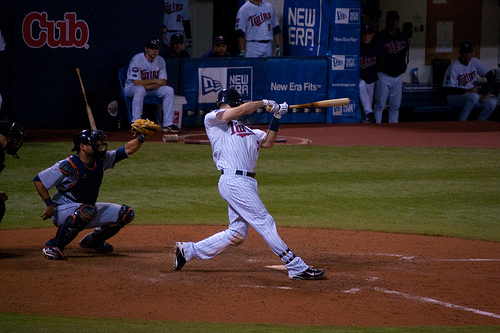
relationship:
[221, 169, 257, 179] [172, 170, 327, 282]
belt in pants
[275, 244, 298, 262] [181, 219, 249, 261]
bands around leg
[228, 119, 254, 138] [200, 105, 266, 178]
name on shirt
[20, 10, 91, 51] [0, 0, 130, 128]
print on wall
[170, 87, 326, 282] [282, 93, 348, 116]
batter holds bat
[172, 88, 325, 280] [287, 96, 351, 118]
batter swings bat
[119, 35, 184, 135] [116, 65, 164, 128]
players in chair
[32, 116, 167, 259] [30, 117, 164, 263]
catcher wears catcher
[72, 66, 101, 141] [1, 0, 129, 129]
bat leans against wall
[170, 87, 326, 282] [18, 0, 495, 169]
batter in dug out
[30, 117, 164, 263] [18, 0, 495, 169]
catcher in dug out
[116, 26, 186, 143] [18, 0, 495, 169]
players in dug out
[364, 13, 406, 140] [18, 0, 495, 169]
players in dug out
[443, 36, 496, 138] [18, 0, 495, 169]
players in dug out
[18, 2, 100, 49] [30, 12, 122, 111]
print on wall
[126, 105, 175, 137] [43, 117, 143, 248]
mit on catcher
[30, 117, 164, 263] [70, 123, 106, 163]
catcher wears mask